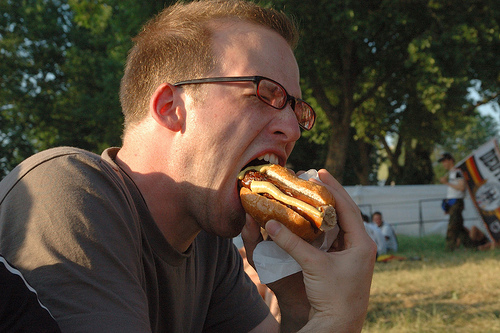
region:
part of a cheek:
[213, 130, 234, 187]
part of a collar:
[151, 232, 186, 259]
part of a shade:
[409, 284, 439, 321]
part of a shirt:
[84, 235, 152, 290]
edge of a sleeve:
[253, 300, 270, 317]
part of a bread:
[253, 180, 303, 219]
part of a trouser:
[446, 207, 463, 236]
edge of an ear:
[158, 112, 188, 148]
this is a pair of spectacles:
[175, 73, 316, 132]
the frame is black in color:
[170, 73, 268, 83]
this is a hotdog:
[245, 162, 336, 242]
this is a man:
[10, 7, 376, 327]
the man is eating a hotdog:
[195, 120, 336, 246]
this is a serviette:
[262, 247, 279, 277]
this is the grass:
[401, 259, 498, 324]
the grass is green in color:
[396, 262, 483, 331]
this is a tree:
[321, 17, 490, 187]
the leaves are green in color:
[399, 42, 468, 114]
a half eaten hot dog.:
[235, 156, 346, 251]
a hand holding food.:
[263, 164, 379, 326]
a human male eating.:
[0, 7, 382, 329]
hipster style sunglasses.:
[159, 63, 317, 131]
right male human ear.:
[147, 75, 186, 134]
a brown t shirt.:
[0, 141, 314, 331]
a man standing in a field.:
[427, 143, 473, 245]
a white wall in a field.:
[341, 185, 487, 227]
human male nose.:
[266, 101, 305, 149]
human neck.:
[135, 153, 235, 263]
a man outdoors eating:
[2, 0, 497, 330]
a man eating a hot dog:
[3, 1, 380, 331]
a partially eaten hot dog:
[234, 159, 340, 249]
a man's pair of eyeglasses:
[171, 71, 320, 133]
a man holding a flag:
[433, 135, 498, 257]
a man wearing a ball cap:
[435, 149, 470, 254]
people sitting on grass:
[359, 207, 400, 257]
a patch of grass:
[377, 261, 497, 331]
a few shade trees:
[316, 1, 499, 183]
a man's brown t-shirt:
[1, 144, 274, 331]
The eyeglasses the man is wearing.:
[224, 73, 322, 123]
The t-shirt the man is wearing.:
[7, 152, 285, 332]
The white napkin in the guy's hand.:
[255, 226, 335, 298]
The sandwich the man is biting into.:
[244, 153, 341, 247]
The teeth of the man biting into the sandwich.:
[261, 143, 289, 165]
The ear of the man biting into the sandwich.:
[145, 71, 189, 141]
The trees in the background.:
[1, 3, 498, 173]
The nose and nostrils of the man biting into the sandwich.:
[271, 109, 306, 153]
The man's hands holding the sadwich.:
[232, 158, 379, 332]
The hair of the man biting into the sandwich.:
[111, 6, 301, 120]